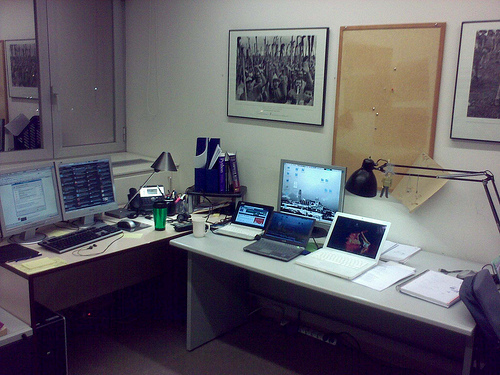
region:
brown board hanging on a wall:
[333, 21, 452, 205]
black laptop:
[208, 197, 274, 242]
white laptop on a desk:
[293, 210, 396, 289]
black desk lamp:
[118, 149, 183, 232]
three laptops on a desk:
[206, 198, 396, 283]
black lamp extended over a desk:
[341, 152, 499, 231]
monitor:
[273, 153, 349, 231]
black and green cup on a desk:
[148, 194, 173, 234]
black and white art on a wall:
[203, 22, 334, 134]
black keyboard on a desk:
[34, 221, 129, 256]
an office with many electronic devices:
[6, 3, 496, 369]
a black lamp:
[337, 153, 499, 239]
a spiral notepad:
[396, 258, 465, 308]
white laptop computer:
[295, 208, 389, 285]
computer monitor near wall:
[269, 153, 356, 219]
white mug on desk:
[183, 213, 230, 263]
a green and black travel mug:
[143, 195, 173, 242]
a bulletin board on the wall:
[330, 15, 448, 187]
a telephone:
[123, 173, 177, 220]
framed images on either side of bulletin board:
[217, 18, 499, 148]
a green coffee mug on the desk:
[146, 190, 168, 232]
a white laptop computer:
[301, 207, 411, 279]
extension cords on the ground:
[260, 290, 366, 363]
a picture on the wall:
[214, 22, 345, 134]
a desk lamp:
[106, 140, 177, 243]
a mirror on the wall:
[0, 0, 122, 160]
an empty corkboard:
[325, 10, 467, 207]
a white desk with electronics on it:
[161, 163, 491, 373]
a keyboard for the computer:
[36, 210, 124, 271]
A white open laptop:
[291, 207, 391, 283]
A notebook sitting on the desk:
[395, 255, 470, 320]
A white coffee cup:
[185, 210, 211, 240]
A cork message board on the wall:
[331, 20, 436, 195]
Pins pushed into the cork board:
[360, 61, 401, 141]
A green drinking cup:
[145, 200, 170, 236]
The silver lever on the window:
[45, 80, 60, 110]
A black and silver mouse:
[110, 215, 135, 235]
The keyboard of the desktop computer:
[36, 225, 125, 251]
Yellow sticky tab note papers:
[17, 255, 67, 277]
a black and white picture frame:
[224, 26, 331, 128]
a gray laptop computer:
[240, 210, 314, 261]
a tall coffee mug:
[148, 192, 169, 232]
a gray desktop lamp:
[106, 147, 183, 220]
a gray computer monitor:
[52, 154, 123, 223]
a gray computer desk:
[170, 215, 493, 374]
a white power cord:
[275, 307, 340, 345]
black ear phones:
[68, 227, 123, 257]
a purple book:
[225, 150, 242, 192]